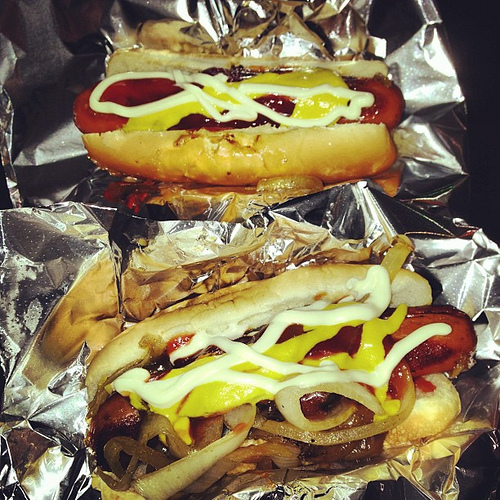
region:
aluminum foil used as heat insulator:
[42, 197, 345, 251]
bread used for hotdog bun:
[90, 265, 335, 315]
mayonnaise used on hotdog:
[203, 332, 250, 360]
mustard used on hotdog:
[364, 325, 382, 360]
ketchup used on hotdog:
[323, 338, 357, 349]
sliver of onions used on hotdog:
[263, 420, 385, 450]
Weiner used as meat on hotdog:
[413, 315, 470, 357]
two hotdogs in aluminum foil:
[78, 45, 475, 492]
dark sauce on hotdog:
[90, 425, 137, 438]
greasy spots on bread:
[141, 138, 324, 166]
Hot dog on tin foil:
[49, 294, 477, 459]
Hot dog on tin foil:
[54, 45, 413, 187]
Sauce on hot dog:
[96, 375, 154, 402]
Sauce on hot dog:
[145, 365, 195, 427]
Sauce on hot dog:
[170, 348, 219, 430]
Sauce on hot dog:
[197, 335, 267, 424]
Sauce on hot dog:
[255, 313, 330, 418]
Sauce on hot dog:
[310, 295, 406, 407]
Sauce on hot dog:
[362, 288, 464, 397]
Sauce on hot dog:
[113, 63, 363, 122]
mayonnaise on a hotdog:
[108, 264, 450, 406]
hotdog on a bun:
[87, 262, 478, 499]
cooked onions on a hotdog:
[92, 358, 419, 498]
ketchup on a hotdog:
[166, 325, 433, 402]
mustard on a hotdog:
[123, 303, 413, 438]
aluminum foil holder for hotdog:
[1, 179, 498, 499]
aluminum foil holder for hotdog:
[0, 0, 475, 212]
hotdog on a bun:
[73, 48, 405, 185]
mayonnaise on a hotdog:
[88, 68, 379, 127]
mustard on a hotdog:
[123, 68, 348, 135]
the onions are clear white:
[274, 393, 306, 420]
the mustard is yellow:
[286, 338, 301, 358]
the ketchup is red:
[338, 336, 350, 348]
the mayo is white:
[286, 307, 316, 328]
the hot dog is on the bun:
[368, 83, 400, 140]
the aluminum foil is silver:
[13, 9, 65, 63]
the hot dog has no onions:
[153, 56, 369, 126]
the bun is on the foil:
[77, 344, 124, 497]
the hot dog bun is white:
[118, 60, 145, 72]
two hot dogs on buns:
[79, 36, 490, 498]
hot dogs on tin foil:
[66, 38, 499, 499]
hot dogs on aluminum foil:
[54, 17, 474, 496]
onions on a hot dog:
[116, 364, 426, 479]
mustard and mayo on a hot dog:
[103, 278, 449, 423]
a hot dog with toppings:
[70, 34, 407, 164]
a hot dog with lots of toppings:
[9, 218, 499, 499]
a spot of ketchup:
[159, 329, 201, 355]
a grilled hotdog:
[384, 312, 486, 374]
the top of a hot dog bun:
[86, 126, 396, 181]